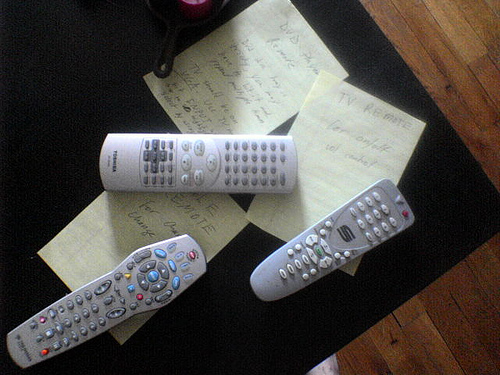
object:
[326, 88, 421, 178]
writing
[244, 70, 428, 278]
paper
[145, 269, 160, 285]
button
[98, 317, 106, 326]
button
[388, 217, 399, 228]
key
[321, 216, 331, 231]
key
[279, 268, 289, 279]
key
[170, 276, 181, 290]
key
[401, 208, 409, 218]
button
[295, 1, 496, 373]
floor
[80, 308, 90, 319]
button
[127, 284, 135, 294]
button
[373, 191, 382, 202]
key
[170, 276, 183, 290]
blue buttons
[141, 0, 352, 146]
rectangular paper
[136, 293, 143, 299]
button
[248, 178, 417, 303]
remote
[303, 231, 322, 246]
button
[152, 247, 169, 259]
button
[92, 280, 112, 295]
button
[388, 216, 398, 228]
key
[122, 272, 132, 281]
button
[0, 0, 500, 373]
black table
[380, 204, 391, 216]
key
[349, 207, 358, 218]
key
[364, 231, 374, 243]
key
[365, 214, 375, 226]
key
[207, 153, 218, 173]
button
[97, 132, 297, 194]
remote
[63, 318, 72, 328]
button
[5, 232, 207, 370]
remote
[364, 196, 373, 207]
key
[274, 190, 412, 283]
keyboard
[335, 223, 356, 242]
s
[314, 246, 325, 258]
buttons